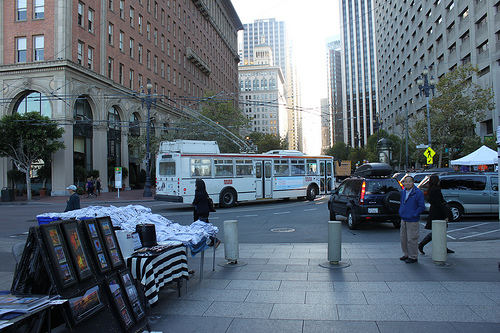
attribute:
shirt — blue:
[397, 190, 427, 223]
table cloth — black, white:
[129, 236, 190, 298]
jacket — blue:
[400, 186, 422, 222]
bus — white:
[157, 140, 338, 197]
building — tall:
[236, 16, 305, 152]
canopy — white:
[441, 146, 499, 167]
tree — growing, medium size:
[1, 111, 53, 203]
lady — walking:
[425, 175, 457, 254]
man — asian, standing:
[395, 173, 426, 265]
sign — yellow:
[419, 146, 438, 159]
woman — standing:
[189, 176, 217, 226]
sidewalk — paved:
[192, 247, 499, 333]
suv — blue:
[326, 175, 406, 227]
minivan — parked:
[421, 178, 492, 214]